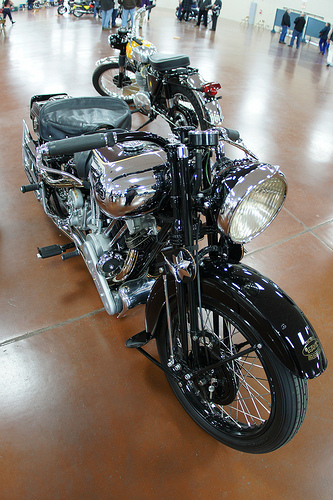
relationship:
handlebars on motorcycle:
[77, 111, 296, 191] [86, 25, 250, 142]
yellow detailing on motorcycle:
[125, 37, 154, 60] [88, 14, 231, 145]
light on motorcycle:
[200, 79, 220, 97] [90, 1, 224, 138]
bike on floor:
[19, 67, 328, 455] [0, 7, 333, 498]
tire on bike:
[144, 327, 322, 484] [27, 52, 324, 460]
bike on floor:
[92, 12, 224, 130] [0, 7, 333, 498]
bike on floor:
[19, 92, 327, 453] [0, 7, 333, 498]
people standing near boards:
[277, 8, 328, 50] [266, 1, 332, 49]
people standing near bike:
[174, 0, 228, 32] [19, 92, 327, 453]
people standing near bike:
[97, 0, 148, 30] [71, 1, 99, 17]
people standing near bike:
[97, 0, 148, 30] [54, 1, 75, 15]